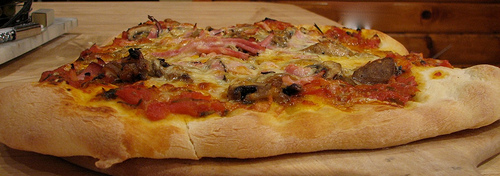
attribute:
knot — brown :
[419, 5, 435, 22]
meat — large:
[348, 62, 420, 81]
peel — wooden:
[59, 128, 499, 173]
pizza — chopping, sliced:
[5, 12, 499, 165]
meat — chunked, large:
[109, 34, 154, 83]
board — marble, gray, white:
[3, 12, 78, 47]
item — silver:
[1, 10, 76, 55]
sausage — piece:
[115, 33, 157, 75]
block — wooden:
[0, 122, 499, 174]